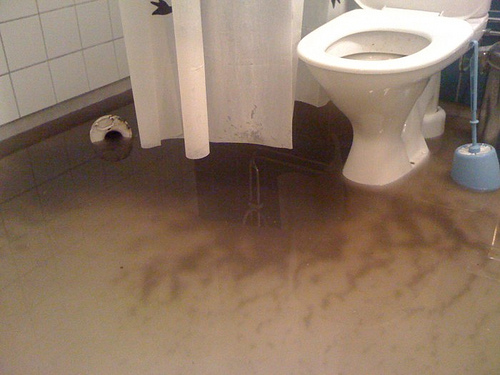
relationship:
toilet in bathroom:
[291, 1, 488, 193] [1, 0, 488, 343]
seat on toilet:
[290, 4, 484, 79] [291, 1, 488, 193]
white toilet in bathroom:
[296, 2, 492, 189] [1, 0, 488, 343]